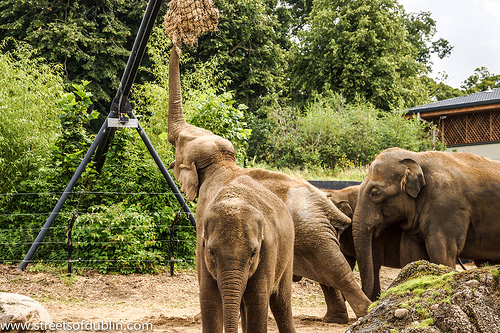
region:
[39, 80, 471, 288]
elephants in an enclosure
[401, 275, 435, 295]
green moss on a stone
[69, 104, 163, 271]
a black metal tripod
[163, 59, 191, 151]
a trunk reaching for nuts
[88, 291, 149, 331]
brown dirt on the ground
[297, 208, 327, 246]
wrinkled gray skin on the elephant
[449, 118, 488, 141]
a latticed wood panel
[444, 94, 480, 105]
a black tar roof on a building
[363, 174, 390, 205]
a dark eye of an elephant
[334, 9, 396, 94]
a tall green tree next to the enclosure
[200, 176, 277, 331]
BROWN BABY AFRICAN ELEPHANT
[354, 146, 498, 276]
BROWN BABY AFRICAN ELEPHANT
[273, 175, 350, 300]
BROWN BABY AFRICAN ELEPHANT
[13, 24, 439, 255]
GREEN TREES IN BACKGROUND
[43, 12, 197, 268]
BLACK METAL POLES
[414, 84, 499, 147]
WOODEN HOUSE OFF TO THE RIGHT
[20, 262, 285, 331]
BROWN DIRT UNDER ELEPHANTS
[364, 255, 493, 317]
GREY ROCK WITH GREEN MOSS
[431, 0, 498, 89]
CLOUDY WHITE SKY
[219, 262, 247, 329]
TRUNK OF AFRICAN ELEPHANT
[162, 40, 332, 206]
elephant reaching for food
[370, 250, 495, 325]
mossy rock inside enclosure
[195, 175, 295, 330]
baby elephant facing camera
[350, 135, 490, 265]
elephant facing to the left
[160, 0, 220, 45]
bag of elephant food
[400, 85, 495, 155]
house for elephant caretaker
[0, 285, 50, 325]
rock inside elephant enclosure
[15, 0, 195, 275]
pole for elephant food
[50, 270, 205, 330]
dirt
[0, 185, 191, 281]
fence to keep elephants in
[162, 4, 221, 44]
nuts in a black net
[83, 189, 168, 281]
a barbed wire fence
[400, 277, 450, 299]
green moss on a gra rock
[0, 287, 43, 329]
a large gray stone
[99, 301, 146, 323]
dry brown dirt on the ground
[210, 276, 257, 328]
a gray elephant trunk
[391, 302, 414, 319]
a small white rock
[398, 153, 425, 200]
a floppy gray ear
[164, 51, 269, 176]
an elephant reaching for nuts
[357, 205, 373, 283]
a long gray elephant trunk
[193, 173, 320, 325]
SMALL BROWN INDIAN ELEPHANT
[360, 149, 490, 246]
SMALL BROWN INDIAN ELEPHANT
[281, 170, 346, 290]
SMALL BROWN INDIAN ELEPHANT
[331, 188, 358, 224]
SMALL BROWN INDIAN ELEPHANT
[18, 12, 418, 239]
GREEN LEAVES ON TREES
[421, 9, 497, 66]
SKY WITH WHITE CLOUDS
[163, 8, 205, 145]
EXTENDED ELEPHANT TRUNK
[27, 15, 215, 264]
METAL BLACK TRIANGULAR FEEDER